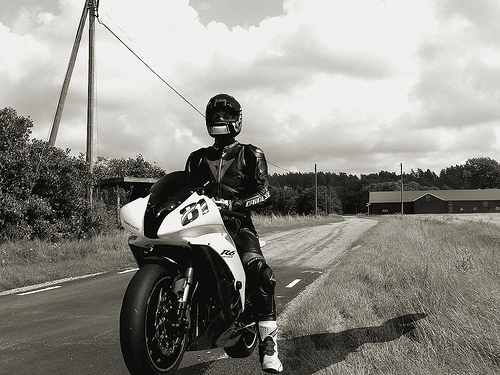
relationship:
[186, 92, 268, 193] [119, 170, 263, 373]
man on motorcycle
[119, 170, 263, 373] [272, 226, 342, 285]
motorcycle in road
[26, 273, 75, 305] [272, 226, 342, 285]
line in road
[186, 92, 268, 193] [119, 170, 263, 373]
man riding motorcycle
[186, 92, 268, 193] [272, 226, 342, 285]
man in road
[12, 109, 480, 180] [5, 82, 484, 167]
tops on horizon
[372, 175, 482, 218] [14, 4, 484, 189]
building during day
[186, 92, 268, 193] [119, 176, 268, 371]
man on motorcycle